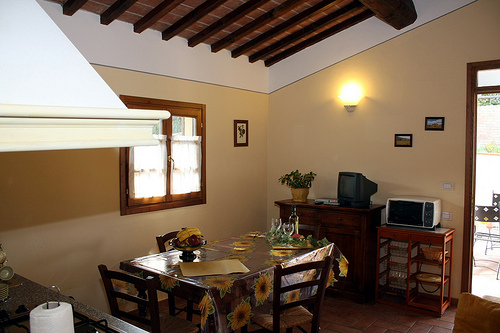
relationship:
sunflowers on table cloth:
[196, 275, 274, 329] [114, 226, 353, 332]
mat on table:
[175, 256, 253, 279] [114, 226, 353, 332]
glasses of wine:
[267, 213, 297, 251] [285, 200, 301, 243]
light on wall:
[331, 72, 373, 114] [269, 55, 459, 173]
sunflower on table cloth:
[204, 272, 238, 296] [114, 226, 353, 332]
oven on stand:
[380, 194, 445, 232] [370, 224, 456, 318]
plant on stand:
[275, 165, 319, 204] [275, 196, 378, 246]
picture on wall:
[389, 131, 415, 149] [269, 55, 459, 173]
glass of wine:
[279, 221, 296, 249] [285, 200, 301, 243]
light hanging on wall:
[331, 72, 373, 114] [269, 55, 459, 173]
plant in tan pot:
[275, 165, 319, 204] [290, 187, 310, 204]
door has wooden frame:
[461, 56, 500, 295] [461, 59, 479, 292]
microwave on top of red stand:
[380, 194, 445, 232] [370, 224, 456, 318]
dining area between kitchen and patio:
[84, 194, 362, 327] [476, 94, 500, 288]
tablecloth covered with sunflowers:
[114, 226, 353, 332] [196, 275, 274, 329]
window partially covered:
[113, 90, 215, 217] [126, 132, 209, 201]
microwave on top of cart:
[380, 194, 445, 232] [370, 224, 456, 318]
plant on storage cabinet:
[275, 165, 319, 204] [275, 196, 378, 246]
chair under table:
[247, 254, 335, 333] [114, 226, 353, 332]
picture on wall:
[422, 114, 450, 132] [269, 55, 459, 173]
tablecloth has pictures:
[114, 226, 353, 332] [196, 275, 274, 329]